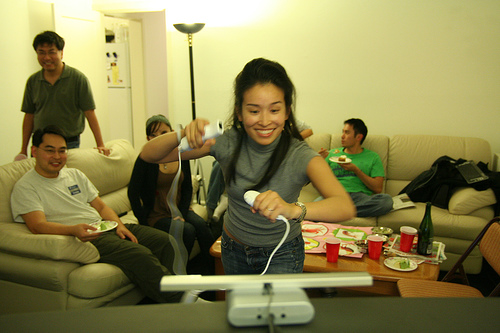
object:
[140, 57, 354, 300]
girl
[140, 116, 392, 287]
wii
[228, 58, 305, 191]
hair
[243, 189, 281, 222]
controller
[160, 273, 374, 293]
bar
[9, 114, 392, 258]
people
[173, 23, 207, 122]
lamp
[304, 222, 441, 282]
table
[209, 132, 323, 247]
shirt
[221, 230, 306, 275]
pants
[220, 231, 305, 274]
jeans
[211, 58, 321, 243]
woman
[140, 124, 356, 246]
remotes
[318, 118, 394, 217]
man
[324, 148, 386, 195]
shirt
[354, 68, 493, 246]
couch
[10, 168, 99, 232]
shirt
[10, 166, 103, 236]
man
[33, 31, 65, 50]
hair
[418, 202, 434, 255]
bottle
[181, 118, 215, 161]
controller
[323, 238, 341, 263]
cup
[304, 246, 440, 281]
table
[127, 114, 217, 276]
remotes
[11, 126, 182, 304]
man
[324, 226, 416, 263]
cups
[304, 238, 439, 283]
table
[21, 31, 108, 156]
man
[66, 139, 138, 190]
sofa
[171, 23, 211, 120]
light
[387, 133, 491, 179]
sofa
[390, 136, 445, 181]
sofa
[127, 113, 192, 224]
woman